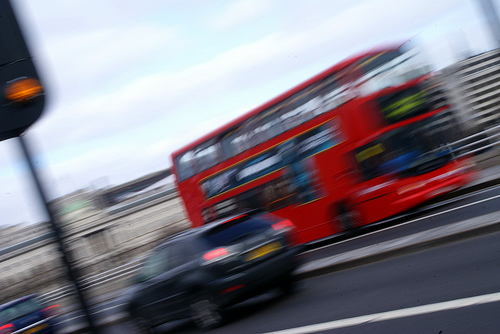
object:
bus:
[168, 34, 479, 246]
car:
[116, 210, 308, 332]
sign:
[196, 116, 351, 202]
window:
[366, 47, 439, 94]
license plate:
[247, 241, 281, 262]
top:
[167, 38, 434, 160]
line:
[262, 291, 499, 333]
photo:
[0, 0, 497, 333]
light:
[0, 75, 43, 100]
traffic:
[0, 164, 499, 334]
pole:
[17, 135, 102, 333]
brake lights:
[271, 219, 294, 232]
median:
[295, 209, 499, 277]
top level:
[167, 37, 450, 213]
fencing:
[452, 123, 499, 158]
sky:
[0, 0, 499, 233]